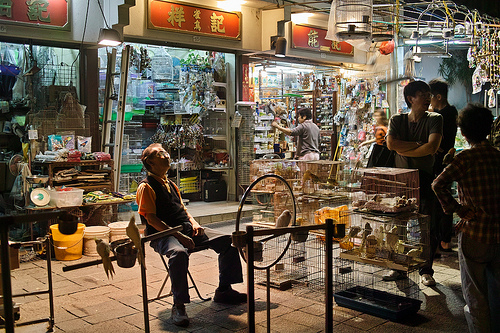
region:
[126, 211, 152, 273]
a small yellow finch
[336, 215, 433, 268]
a cage full of birds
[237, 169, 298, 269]
a large metal hoop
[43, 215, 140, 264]
a row of plastic buckets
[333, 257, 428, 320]
a cage with a blue bottom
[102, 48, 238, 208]
an open pet store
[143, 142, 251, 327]
a man sitting on a stool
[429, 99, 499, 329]
a person in a flannel shirt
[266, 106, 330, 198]
a person shopping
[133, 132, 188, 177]
head of a person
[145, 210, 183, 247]
arm of a person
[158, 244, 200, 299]
leg of a person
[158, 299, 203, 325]
feet of a person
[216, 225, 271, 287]
leg of a person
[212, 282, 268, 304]
feet of a person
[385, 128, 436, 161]
arm of a person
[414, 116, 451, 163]
arm of a person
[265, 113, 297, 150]
arm of a person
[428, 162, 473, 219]
arm of a person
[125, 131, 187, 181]
head of a person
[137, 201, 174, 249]
arm of a person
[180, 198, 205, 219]
arm of a person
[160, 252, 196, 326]
leg of a person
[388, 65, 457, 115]
head of a person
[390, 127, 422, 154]
arm of a person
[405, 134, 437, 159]
arm of a person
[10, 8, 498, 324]
people in the chinese store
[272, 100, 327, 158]
man standing in front of a display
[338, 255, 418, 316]
cage on the floor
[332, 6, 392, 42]
birdcages on the ceiling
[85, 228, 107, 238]
top of the white bucket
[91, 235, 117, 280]
bird sitting on a bar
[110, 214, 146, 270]
metal feeder bucket for the bird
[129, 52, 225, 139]
storefront display in the store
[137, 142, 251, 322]
A man with glasses sitting outside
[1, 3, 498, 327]
An oriental market place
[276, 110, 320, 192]
A guy in a grey long sleeve shirt browsing through items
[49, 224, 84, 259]
A yellow 5 gallon bucket with white handle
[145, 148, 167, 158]
A pair of corrective glasses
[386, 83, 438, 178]
A man standing with folded arms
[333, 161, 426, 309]
Stacked cages of livestock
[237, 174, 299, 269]
A dark color metal hoop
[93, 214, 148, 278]
free roaming birds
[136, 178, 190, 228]
A dark colored vest over a short sleeved orange shirt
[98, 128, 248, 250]
person on the chair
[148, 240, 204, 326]
leg of the person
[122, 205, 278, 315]
pants on the person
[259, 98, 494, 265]
people next to the man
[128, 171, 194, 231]
clothing on the man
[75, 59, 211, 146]
items in the place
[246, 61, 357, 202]
person in a gray shirt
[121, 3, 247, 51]
sign above the ground